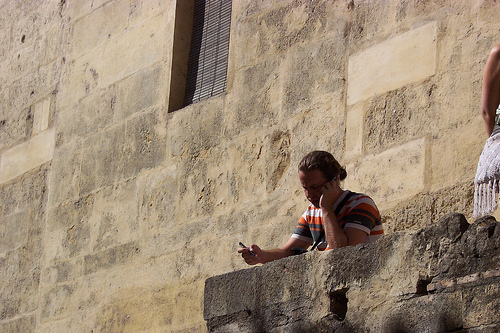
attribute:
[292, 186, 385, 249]
shirt — striped, short sleeve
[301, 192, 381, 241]
shirt — striped, orange, blue, white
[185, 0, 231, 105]
blinds — brown, wooden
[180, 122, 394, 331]
man — standing outside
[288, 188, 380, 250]
shirt — striped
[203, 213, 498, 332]
balcony — stone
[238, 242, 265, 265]
hand — right hand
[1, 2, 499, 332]
building — large, brick, cement block